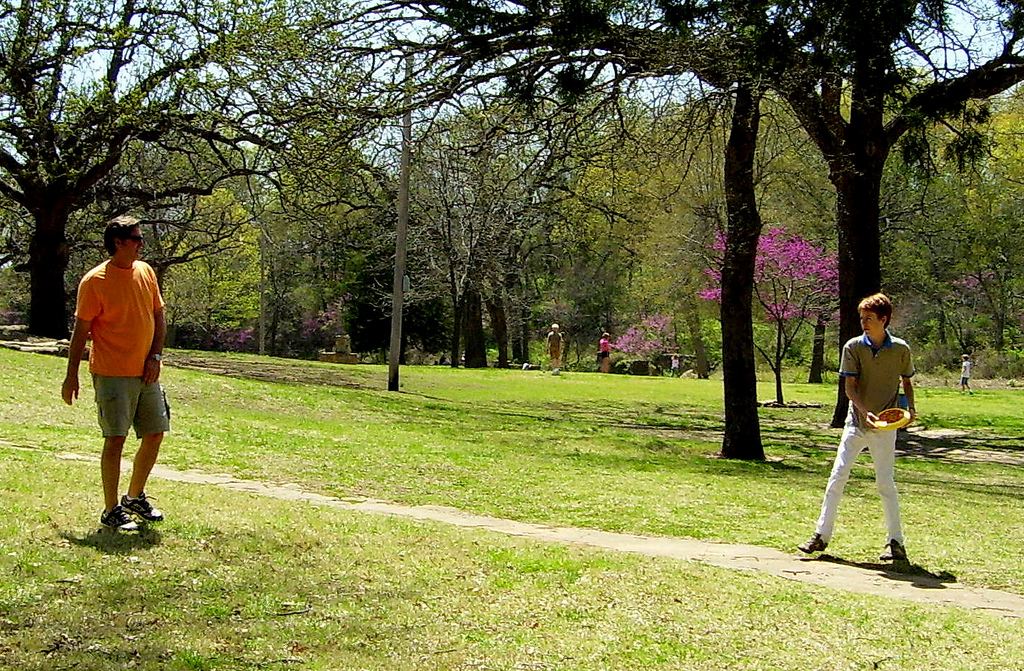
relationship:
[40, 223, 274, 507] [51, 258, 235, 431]
man in shirt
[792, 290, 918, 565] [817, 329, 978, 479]
boy in shirt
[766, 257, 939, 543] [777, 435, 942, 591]
boy in pants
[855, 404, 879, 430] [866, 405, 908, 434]
hand throwing frisbee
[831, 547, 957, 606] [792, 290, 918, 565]
shadow of boy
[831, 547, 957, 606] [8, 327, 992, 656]
shadow on ground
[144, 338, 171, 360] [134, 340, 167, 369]
watch on wrist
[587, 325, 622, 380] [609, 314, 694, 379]
person next to bush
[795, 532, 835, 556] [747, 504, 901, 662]
foot above ground